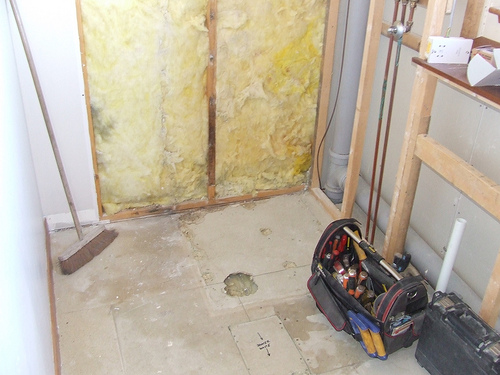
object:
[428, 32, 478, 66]
outlet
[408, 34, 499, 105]
shelf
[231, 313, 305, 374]
tile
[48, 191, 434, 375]
floor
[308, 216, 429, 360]
box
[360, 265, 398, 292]
tool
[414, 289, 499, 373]
case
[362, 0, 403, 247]
tube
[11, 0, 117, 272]
broom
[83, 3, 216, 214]
insulation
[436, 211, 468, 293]
pipe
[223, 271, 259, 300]
drain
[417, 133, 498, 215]
wood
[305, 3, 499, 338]
wall